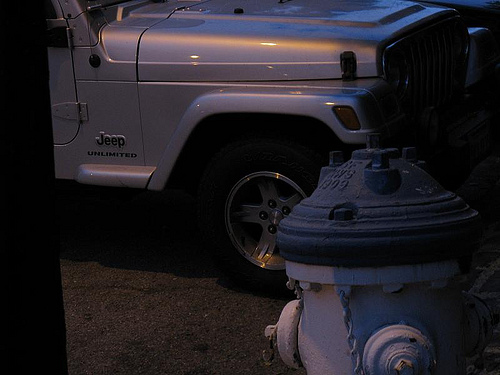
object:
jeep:
[2, 3, 495, 291]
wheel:
[204, 144, 341, 285]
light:
[328, 97, 363, 136]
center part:
[226, 169, 292, 271]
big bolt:
[257, 210, 272, 221]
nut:
[267, 222, 278, 235]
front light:
[366, 25, 414, 95]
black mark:
[337, 49, 361, 94]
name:
[82, 129, 144, 164]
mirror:
[32, 9, 74, 55]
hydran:
[248, 133, 480, 375]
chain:
[331, 293, 369, 373]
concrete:
[65, 251, 271, 372]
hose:
[353, 318, 446, 375]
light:
[188, 52, 200, 60]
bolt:
[259, 319, 281, 354]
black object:
[184, 336, 215, 357]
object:
[230, 4, 251, 19]